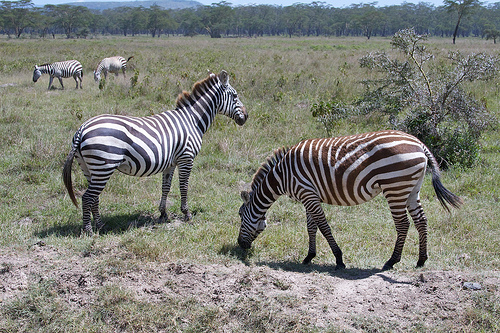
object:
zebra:
[62, 69, 248, 236]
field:
[0, 29, 500, 332]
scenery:
[6, 28, 462, 301]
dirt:
[208, 277, 333, 315]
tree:
[197, 6, 279, 35]